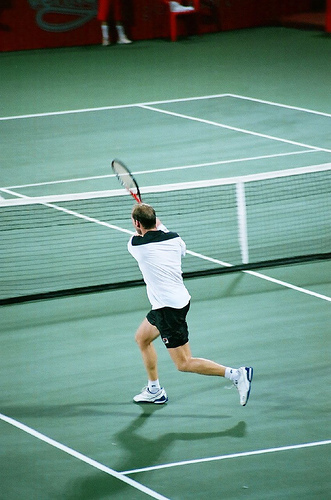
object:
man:
[127, 203, 253, 407]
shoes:
[133, 365, 254, 408]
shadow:
[54, 400, 245, 499]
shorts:
[145, 299, 191, 350]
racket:
[111, 158, 142, 203]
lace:
[141, 384, 148, 394]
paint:
[0, 21, 331, 500]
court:
[0, 20, 331, 500]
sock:
[225, 366, 241, 382]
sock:
[148, 379, 161, 393]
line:
[243, 269, 331, 302]